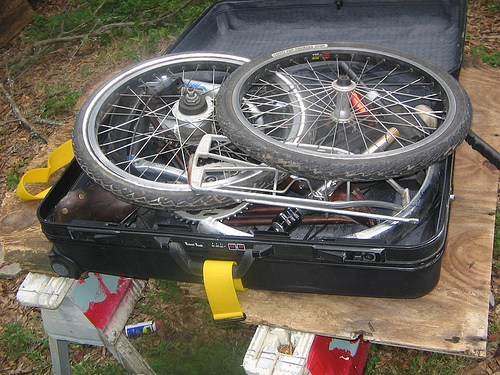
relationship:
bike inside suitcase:
[72, 41, 473, 248] [36, 2, 468, 296]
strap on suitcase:
[200, 260, 249, 324] [36, 2, 468, 296]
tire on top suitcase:
[218, 39, 473, 179] [36, 2, 468, 296]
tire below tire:
[72, 46, 318, 206] [218, 39, 473, 179]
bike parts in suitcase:
[72, 41, 473, 248] [36, 2, 468, 296]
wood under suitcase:
[1, 68, 498, 359] [36, 2, 468, 296]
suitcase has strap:
[36, 2, 468, 296] [200, 260, 249, 324]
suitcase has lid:
[36, 2, 468, 296] [166, 2, 464, 72]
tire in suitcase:
[218, 39, 473, 179] [36, 2, 468, 296]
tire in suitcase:
[72, 46, 318, 206] [36, 2, 468, 296]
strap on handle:
[200, 260, 249, 324] [155, 237, 275, 279]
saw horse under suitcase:
[15, 272, 159, 371] [36, 2, 468, 296]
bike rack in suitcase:
[203, 133, 443, 242] [36, 2, 468, 296]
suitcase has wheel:
[36, 2, 468, 296] [44, 250, 77, 278]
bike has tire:
[72, 41, 473, 248] [218, 39, 473, 179]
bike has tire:
[72, 41, 473, 248] [72, 46, 318, 206]